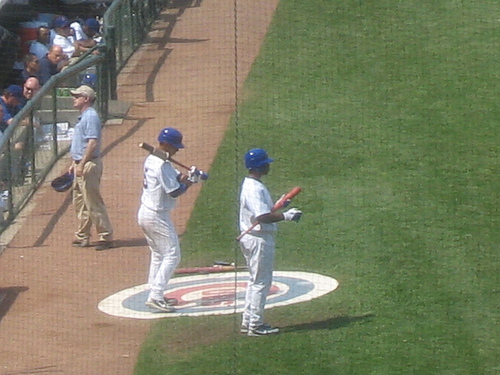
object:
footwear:
[247, 323, 281, 336]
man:
[235, 144, 302, 339]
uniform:
[236, 176, 277, 326]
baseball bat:
[171, 267, 246, 273]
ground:
[94, 259, 342, 321]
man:
[57, 82, 110, 257]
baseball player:
[133, 134, 205, 175]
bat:
[135, 137, 208, 184]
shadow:
[275, 309, 377, 333]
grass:
[138, 57, 500, 374]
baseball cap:
[68, 71, 105, 99]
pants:
[68, 159, 114, 242]